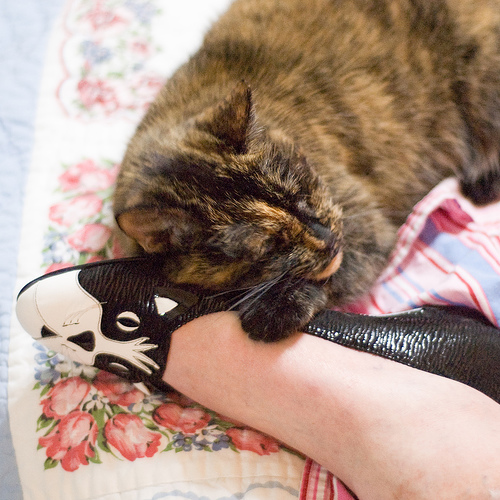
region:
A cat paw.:
[225, 282, 340, 352]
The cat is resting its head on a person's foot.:
[0, 80, 445, 445]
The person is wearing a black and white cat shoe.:
[1, 242, 491, 444]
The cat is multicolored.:
[116, 8, 491, 333]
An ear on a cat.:
[181, 66, 296, 163]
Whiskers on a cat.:
[196, 246, 331, 326]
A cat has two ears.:
[111, 80, 263, 260]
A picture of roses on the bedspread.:
[35, 378, 166, 476]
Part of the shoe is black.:
[395, 322, 486, 357]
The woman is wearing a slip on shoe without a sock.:
[10, 241, 498, 412]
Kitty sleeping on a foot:
[75, 5, 479, 442]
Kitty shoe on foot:
[3, 231, 338, 438]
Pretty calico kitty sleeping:
[102, 6, 472, 350]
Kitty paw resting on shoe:
[186, 251, 351, 363]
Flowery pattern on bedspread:
[18, 5, 258, 467]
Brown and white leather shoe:
[28, 250, 497, 388]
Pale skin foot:
[152, 295, 489, 480]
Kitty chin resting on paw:
[141, 114, 358, 331]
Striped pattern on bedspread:
[338, 176, 498, 300]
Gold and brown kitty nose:
[283, 210, 341, 257]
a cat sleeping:
[110, 5, 467, 287]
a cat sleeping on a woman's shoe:
[116, 126, 371, 361]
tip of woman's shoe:
[6, 255, 181, 385]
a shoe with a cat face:
[26, 250, 166, 395]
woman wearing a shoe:
[26, 255, 492, 421]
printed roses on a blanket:
[36, 379, 188, 462]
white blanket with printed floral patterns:
[51, 17, 138, 172]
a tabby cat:
[129, 30, 486, 309]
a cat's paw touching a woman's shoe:
[238, 271, 337, 342]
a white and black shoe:
[33, 270, 495, 370]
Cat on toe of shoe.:
[45, 260, 146, 401]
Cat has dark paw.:
[231, 275, 336, 352]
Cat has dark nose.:
[306, 224, 342, 254]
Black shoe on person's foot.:
[340, 312, 447, 457]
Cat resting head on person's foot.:
[184, 202, 341, 443]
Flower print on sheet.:
[50, 362, 195, 494]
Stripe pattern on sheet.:
[420, 245, 497, 286]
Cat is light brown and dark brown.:
[266, 47, 492, 201]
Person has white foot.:
[215, 327, 438, 473]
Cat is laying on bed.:
[109, 62, 446, 387]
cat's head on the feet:
[81, 65, 404, 489]